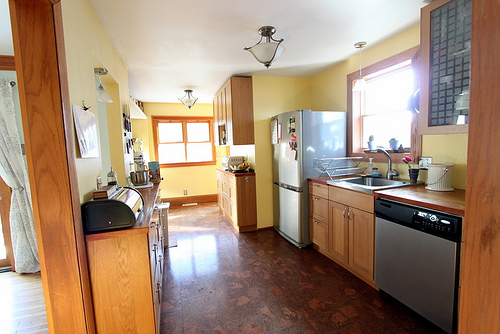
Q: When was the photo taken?
A: Daytime.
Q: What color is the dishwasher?
A: Silver.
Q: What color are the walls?
A: Yellow.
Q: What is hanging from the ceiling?
A: A light.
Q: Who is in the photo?
A: Nobody.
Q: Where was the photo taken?
A: In a kitchen.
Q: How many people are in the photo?
A: None.